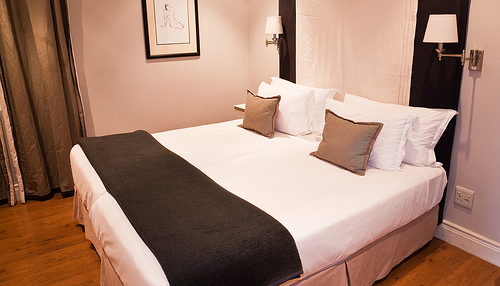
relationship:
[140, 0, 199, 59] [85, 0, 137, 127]
picture on wall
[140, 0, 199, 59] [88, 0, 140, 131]
picture on wall